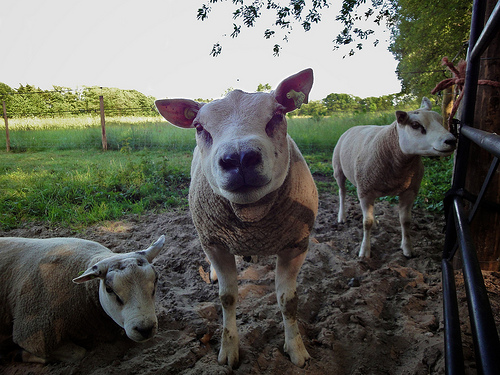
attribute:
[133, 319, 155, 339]
nose — lying down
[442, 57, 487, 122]
rope — red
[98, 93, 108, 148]
post — brown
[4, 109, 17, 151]
post — brown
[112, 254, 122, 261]
hair — short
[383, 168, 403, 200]
ground — three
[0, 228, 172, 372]
sheep — lying down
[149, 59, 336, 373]
sheep — white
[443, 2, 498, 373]
gate — black, railed, metal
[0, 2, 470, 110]
trees — green, lush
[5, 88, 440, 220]
grass — tall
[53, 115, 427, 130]
grass — tall, green, soft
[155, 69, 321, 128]
ears — pink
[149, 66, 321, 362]
sheep — standing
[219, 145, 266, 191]
nose — black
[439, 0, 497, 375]
fence — black, iron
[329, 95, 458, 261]
sheep — standing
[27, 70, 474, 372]
sheep — group of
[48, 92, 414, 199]
field — grassy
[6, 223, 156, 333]
sheep — lying down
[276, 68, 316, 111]
ear — pink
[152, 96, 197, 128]
ear — pink